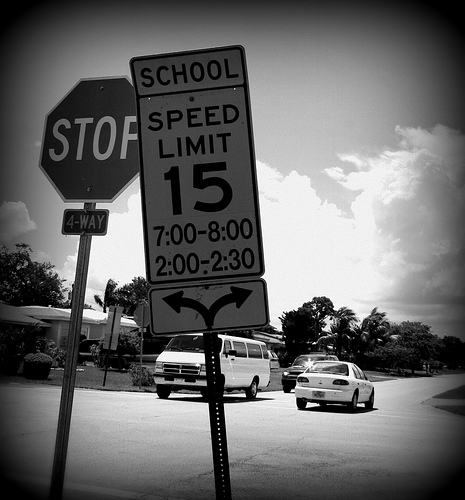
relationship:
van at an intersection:
[150, 320, 272, 398] [1, 367, 464, 496]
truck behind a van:
[280, 353, 339, 392] [150, 320, 272, 398]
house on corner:
[0, 303, 52, 367] [0, 352, 383, 396]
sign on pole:
[102, 303, 123, 349] [103, 308, 116, 384]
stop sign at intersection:
[39, 74, 145, 235] [4, 379, 460, 497]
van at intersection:
[152, 330, 270, 397] [4, 379, 460, 497]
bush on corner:
[20, 348, 52, 379] [5, 0, 116, 381]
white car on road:
[292, 356, 375, 413] [17, 352, 441, 482]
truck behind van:
[280, 353, 339, 392] [152, 332, 270, 399]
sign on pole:
[37, 75, 141, 206] [45, 204, 98, 493]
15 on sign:
[163, 161, 230, 213] [129, 45, 265, 284]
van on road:
[150, 334, 278, 400] [9, 350, 463, 498]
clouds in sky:
[0, 114, 460, 340] [0, 2, 460, 114]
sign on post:
[102, 303, 123, 349] [96, 310, 124, 391]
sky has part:
[138, 44, 454, 257] [260, 21, 450, 151]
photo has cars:
[10, 8, 451, 485] [151, 330, 376, 413]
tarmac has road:
[9, 366, 450, 485] [1, 372, 464, 498]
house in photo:
[0, 303, 49, 367] [10, 8, 451, 485]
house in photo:
[22, 300, 136, 359] [10, 8, 451, 485]